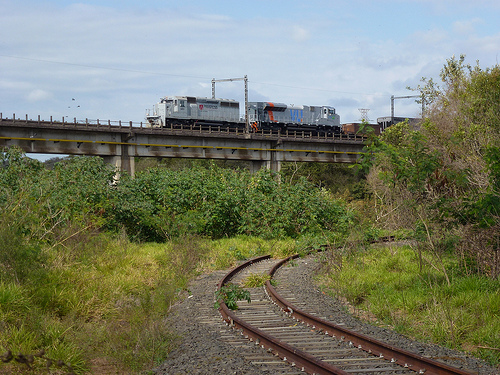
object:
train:
[144, 95, 338, 135]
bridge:
[0, 113, 376, 164]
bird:
[77, 104, 80, 108]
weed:
[214, 281, 252, 311]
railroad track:
[218, 235, 479, 373]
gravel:
[291, 263, 330, 307]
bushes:
[110, 165, 354, 243]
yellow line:
[0, 136, 378, 156]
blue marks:
[290, 108, 304, 123]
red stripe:
[268, 101, 274, 121]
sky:
[0, 0, 500, 123]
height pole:
[243, 76, 251, 134]